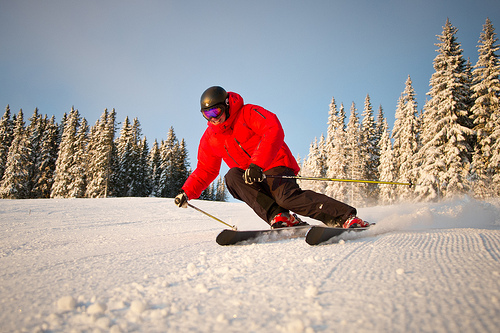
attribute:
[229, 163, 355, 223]
pants — black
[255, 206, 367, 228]
shoes — black, red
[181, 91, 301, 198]
jacket — red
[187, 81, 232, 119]
man's helmet — black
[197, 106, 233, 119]
google lens — tinted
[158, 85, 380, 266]
man wearing jacket — orange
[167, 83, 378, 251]
man wearing pants — brown, black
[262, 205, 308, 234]
man's boot — orange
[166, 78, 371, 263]
man using pole — pushing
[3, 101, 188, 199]
pine trees — dusted, snowy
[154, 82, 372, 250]
man wearing glove — warm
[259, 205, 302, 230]
shoe — red